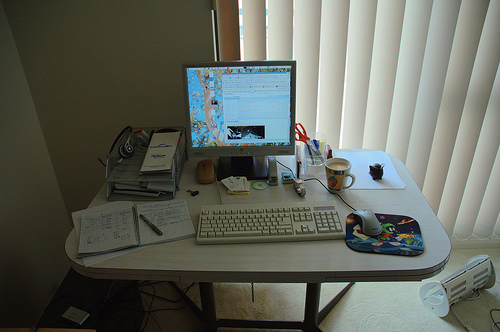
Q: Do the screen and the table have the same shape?
A: Yes, both the screen and the table are square.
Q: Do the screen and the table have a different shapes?
A: No, both the screen and the table are square.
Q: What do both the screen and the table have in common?
A: The shape, both the screen and the table are square.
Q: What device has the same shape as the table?
A: The screen is the same shape as the table.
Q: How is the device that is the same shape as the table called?
A: The device is a screen.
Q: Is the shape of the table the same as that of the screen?
A: Yes, both the table and the screen are square.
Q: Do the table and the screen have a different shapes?
A: No, both the table and the screen are square.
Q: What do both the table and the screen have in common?
A: The shape, both the table and the screen are square.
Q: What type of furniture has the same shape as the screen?
A: The table is the same shape as the screen.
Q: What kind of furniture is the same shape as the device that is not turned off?
A: The table is the same shape as the screen.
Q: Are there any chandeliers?
A: No, there are no chandeliers.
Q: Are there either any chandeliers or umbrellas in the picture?
A: No, there are no chandeliers or umbrellas.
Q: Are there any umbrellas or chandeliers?
A: No, there are no chandeliers or umbrellas.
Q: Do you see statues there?
A: No, there are no statues.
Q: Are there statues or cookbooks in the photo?
A: No, there are no statues or cookbooks.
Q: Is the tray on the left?
A: Yes, the tray is on the left of the image.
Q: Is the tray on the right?
A: No, the tray is on the left of the image.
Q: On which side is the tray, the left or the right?
A: The tray is on the left of the image.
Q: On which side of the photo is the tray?
A: The tray is on the left of the image.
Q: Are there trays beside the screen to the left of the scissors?
A: Yes, there is a tray beside the screen.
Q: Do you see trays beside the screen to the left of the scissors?
A: Yes, there is a tray beside the screen.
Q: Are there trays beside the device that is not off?
A: Yes, there is a tray beside the screen.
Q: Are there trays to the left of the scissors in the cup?
A: Yes, there is a tray to the left of the scissors.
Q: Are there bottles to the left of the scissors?
A: No, there is a tray to the left of the scissors.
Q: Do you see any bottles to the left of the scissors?
A: No, there is a tray to the left of the scissors.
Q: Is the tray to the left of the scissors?
A: Yes, the tray is to the left of the scissors.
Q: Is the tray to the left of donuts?
A: No, the tray is to the left of the scissors.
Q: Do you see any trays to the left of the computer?
A: Yes, there is a tray to the left of the computer.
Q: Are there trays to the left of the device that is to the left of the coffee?
A: Yes, there is a tray to the left of the computer.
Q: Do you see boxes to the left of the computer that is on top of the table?
A: No, there is a tray to the left of the computer.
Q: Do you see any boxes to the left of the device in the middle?
A: No, there is a tray to the left of the computer.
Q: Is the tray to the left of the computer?
A: Yes, the tray is to the left of the computer.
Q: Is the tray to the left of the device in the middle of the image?
A: Yes, the tray is to the left of the computer.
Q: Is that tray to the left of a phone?
A: No, the tray is to the left of the computer.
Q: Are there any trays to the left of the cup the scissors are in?
A: Yes, there is a tray to the left of the cup.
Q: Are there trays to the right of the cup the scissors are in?
A: No, the tray is to the left of the cup.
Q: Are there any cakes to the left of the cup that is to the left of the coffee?
A: No, there is a tray to the left of the cup.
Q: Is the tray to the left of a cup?
A: Yes, the tray is to the left of a cup.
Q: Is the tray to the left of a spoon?
A: No, the tray is to the left of a cup.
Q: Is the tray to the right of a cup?
A: No, the tray is to the left of a cup.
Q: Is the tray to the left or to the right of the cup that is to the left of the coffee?
A: The tray is to the left of the cup.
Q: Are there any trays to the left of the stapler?
A: Yes, there is a tray to the left of the stapler.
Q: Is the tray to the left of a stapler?
A: Yes, the tray is to the left of a stapler.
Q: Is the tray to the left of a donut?
A: No, the tray is to the left of a stapler.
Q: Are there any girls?
A: No, there are no girls.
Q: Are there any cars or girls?
A: No, there are no girls or cars.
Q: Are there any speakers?
A: No, there are no speakers.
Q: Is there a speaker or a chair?
A: No, there are no speakers or chairs.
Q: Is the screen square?
A: Yes, the screen is square.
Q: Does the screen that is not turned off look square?
A: Yes, the screen is square.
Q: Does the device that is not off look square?
A: Yes, the screen is square.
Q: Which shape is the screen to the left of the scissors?
A: The screen is square.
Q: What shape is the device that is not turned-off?
A: The screen is square.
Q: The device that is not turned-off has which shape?
A: The screen is square.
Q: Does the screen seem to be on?
A: Yes, the screen is on.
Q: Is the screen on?
A: Yes, the screen is on.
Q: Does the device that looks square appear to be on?
A: Yes, the screen is on.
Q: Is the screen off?
A: No, the screen is on.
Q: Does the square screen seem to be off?
A: No, the screen is on.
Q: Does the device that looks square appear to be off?
A: No, the screen is on.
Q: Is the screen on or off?
A: The screen is on.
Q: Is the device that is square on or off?
A: The screen is on.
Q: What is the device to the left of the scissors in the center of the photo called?
A: The device is a screen.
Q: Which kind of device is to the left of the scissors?
A: The device is a screen.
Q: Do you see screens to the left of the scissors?
A: Yes, there is a screen to the left of the scissors.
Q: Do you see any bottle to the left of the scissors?
A: No, there is a screen to the left of the scissors.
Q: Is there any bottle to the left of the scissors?
A: No, there is a screen to the left of the scissors.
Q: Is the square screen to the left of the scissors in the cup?
A: Yes, the screen is to the left of the scissors.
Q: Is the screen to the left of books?
A: No, the screen is to the left of the scissors.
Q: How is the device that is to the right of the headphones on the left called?
A: The device is a screen.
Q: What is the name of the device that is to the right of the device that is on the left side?
A: The device is a screen.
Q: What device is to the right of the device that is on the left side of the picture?
A: The device is a screen.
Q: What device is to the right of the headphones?
A: The device is a screen.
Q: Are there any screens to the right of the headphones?
A: Yes, there is a screen to the right of the headphones.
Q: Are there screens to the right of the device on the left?
A: Yes, there is a screen to the right of the headphones.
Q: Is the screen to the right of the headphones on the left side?
A: Yes, the screen is to the right of the headphones.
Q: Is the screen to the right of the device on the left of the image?
A: Yes, the screen is to the right of the headphones.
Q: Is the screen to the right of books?
A: No, the screen is to the right of the headphones.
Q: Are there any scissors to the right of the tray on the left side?
A: Yes, there are scissors to the right of the tray.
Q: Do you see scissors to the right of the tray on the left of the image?
A: Yes, there are scissors to the right of the tray.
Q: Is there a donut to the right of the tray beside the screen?
A: No, there are scissors to the right of the tray.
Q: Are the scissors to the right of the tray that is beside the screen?
A: Yes, the scissors are to the right of the tray.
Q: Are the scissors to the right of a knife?
A: No, the scissors are to the right of the tray.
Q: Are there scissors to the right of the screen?
A: Yes, there are scissors to the right of the screen.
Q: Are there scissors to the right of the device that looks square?
A: Yes, there are scissors to the right of the screen.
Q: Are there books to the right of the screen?
A: No, there are scissors to the right of the screen.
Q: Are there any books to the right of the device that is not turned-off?
A: No, there are scissors to the right of the screen.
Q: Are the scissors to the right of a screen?
A: Yes, the scissors are to the right of a screen.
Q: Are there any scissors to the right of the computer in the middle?
A: Yes, there are scissors to the right of the computer.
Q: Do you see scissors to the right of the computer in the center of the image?
A: Yes, there are scissors to the right of the computer.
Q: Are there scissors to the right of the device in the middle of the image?
A: Yes, there are scissors to the right of the computer.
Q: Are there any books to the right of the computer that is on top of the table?
A: No, there are scissors to the right of the computer.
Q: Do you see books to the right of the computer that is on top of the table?
A: No, there are scissors to the right of the computer.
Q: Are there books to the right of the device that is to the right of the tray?
A: No, there are scissors to the right of the computer.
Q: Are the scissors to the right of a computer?
A: Yes, the scissors are to the right of a computer.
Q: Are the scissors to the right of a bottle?
A: No, the scissors are to the right of a computer.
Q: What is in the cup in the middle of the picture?
A: The scissors are in the cup.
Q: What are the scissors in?
A: The scissors are in the cup.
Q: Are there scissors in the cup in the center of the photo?
A: Yes, there are scissors in the cup.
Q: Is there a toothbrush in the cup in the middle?
A: No, there are scissors in the cup.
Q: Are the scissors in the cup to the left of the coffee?
A: Yes, the scissors are in the cup.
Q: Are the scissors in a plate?
A: No, the scissors are in the cup.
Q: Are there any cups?
A: Yes, there is a cup.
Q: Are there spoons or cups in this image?
A: Yes, there is a cup.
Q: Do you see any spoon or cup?
A: Yes, there is a cup.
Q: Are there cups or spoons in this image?
A: Yes, there is a cup.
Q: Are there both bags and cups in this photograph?
A: No, there is a cup but no bags.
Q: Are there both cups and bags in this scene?
A: No, there is a cup but no bags.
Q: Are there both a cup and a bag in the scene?
A: No, there is a cup but no bags.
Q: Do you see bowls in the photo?
A: No, there are no bowls.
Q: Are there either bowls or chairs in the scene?
A: No, there are no bowls or chairs.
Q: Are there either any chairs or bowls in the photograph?
A: No, there are no bowls or chairs.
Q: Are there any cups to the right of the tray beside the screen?
A: Yes, there is a cup to the right of the tray.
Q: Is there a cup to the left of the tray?
A: No, the cup is to the right of the tray.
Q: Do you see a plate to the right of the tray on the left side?
A: No, there is a cup to the right of the tray.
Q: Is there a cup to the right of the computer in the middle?
A: Yes, there is a cup to the right of the computer.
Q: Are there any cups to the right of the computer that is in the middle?
A: Yes, there is a cup to the right of the computer.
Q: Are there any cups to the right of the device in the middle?
A: Yes, there is a cup to the right of the computer.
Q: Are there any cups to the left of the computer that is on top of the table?
A: No, the cup is to the right of the computer.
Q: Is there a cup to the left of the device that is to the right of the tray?
A: No, the cup is to the right of the computer.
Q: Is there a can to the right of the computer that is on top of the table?
A: No, there is a cup to the right of the computer.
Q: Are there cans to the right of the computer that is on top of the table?
A: No, there is a cup to the right of the computer.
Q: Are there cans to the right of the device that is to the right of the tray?
A: No, there is a cup to the right of the computer.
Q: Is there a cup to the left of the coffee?
A: Yes, there is a cup to the left of the coffee.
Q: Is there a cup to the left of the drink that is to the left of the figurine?
A: Yes, there is a cup to the left of the coffee.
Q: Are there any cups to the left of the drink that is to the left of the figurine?
A: Yes, there is a cup to the left of the coffee.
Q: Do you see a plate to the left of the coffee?
A: No, there is a cup to the left of the coffee.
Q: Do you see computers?
A: Yes, there is a computer.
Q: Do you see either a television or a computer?
A: Yes, there is a computer.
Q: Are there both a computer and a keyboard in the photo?
A: Yes, there are both a computer and a keyboard.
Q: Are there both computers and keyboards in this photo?
A: Yes, there are both a computer and a keyboard.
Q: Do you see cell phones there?
A: No, there are no cell phones.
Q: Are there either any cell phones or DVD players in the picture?
A: No, there are no cell phones or DVD players.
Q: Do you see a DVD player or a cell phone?
A: No, there are no cell phones or DVD players.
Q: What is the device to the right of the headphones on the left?
A: The device is a computer.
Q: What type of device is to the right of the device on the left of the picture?
A: The device is a computer.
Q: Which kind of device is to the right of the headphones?
A: The device is a computer.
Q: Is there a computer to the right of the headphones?
A: Yes, there is a computer to the right of the headphones.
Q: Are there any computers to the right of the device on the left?
A: Yes, there is a computer to the right of the headphones.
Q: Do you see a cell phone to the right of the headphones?
A: No, there is a computer to the right of the headphones.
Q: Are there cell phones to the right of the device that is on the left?
A: No, there is a computer to the right of the headphones.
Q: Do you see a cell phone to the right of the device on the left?
A: No, there is a computer to the right of the headphones.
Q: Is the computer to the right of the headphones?
A: Yes, the computer is to the right of the headphones.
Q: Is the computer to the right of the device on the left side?
A: Yes, the computer is to the right of the headphones.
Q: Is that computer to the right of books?
A: No, the computer is to the right of the headphones.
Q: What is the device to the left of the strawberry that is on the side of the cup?
A: The device is a computer.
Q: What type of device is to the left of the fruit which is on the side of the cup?
A: The device is a computer.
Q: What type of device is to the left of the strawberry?
A: The device is a computer.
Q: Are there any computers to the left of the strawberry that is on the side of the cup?
A: Yes, there is a computer to the left of the strawberry.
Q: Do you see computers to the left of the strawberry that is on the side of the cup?
A: Yes, there is a computer to the left of the strawberry.